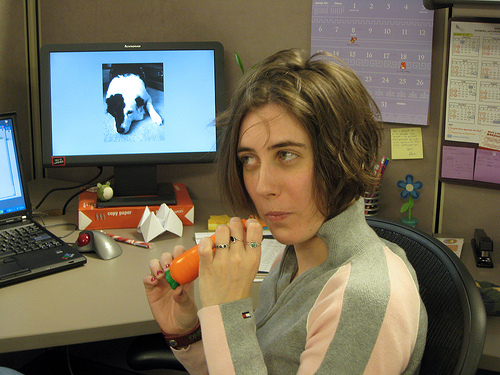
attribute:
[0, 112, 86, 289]
computer — laptop, black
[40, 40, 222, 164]
screen — on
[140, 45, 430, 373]
woman — young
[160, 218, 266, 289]
carrot — fake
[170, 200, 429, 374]
shirt — gray, pink, grey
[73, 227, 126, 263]
mouse — silver, gray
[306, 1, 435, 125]
calendar — purple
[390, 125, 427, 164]
note — yellow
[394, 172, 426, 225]
flower — fake, wooden, blue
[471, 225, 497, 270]
stapler — black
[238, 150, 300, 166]
eyes — open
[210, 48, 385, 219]
hair — brown, short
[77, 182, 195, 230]
box — orange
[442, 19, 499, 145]
calendar — white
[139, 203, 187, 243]
toy — paper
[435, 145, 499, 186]
notes — purple